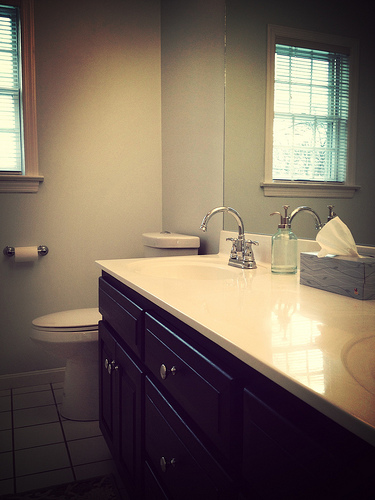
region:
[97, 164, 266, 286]
Bathroom sink.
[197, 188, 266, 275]
Sink on the vanity.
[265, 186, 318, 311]
Soap dispenser on the vanity.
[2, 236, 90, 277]
Toilet paper holder on the wall.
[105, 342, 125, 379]
Vanity cabinet knobs.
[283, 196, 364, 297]
Tissue box on the vanity.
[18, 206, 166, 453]
Toilet in the bathroom.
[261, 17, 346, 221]
Window reflection in the mirror.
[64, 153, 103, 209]
Bathroom wall.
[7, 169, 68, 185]
Window sill in the bathroom.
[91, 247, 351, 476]
dark vanity with silver hardware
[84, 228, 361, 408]
long white countertop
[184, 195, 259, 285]
curve of faucet over sink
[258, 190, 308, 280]
pump bottle with greenish glass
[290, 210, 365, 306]
tissues in wavy grey box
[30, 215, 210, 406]
toilet in corner of bathroom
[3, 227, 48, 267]
roll of toilet paper on holder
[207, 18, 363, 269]
mirrored wall behind counter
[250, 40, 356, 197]
mini blinds in open position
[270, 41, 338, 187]
branches outside of window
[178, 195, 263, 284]
Silver sink faucets.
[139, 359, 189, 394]
Silver hardware on a drawer.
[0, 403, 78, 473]
Black and white floor tile.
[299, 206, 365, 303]
White tissue in a box.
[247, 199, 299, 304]
Silver and clear soap dispenser.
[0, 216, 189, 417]
White toilet in bathroom.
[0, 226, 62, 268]
Silver toilet paper holder.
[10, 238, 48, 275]
A roll of toilet paper.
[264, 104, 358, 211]
Reflection of window in a mirror.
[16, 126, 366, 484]
Bathroom with toilet sink and mirror.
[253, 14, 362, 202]
Reflection of mirror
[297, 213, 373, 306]
Facial Tissue on counter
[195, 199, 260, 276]
Chrome bathroom sink faucet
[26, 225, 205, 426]
Porcelain toilet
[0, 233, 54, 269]
Roll of toilet paper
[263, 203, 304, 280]
Hand soap dispenser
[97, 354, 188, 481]
Silver drawer pulls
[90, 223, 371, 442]
White bathroom counter top with sinks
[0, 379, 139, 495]
Tile and grout bathroom floor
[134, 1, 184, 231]
Corner of the bathroom behind toilet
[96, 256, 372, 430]
dressing area with two sinks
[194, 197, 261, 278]
a stainless steel faucet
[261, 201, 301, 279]
a nearly empty soap dispenser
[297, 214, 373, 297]
a dispenser of facial tissue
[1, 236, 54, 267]
a toilet paper dispenser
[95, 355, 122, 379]
knobs on a cabinet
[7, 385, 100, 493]
a tile floor in a bathroom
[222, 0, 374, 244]
a large mirror in a bathroom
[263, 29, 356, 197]
reflection of a window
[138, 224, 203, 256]
top of a toilet tank